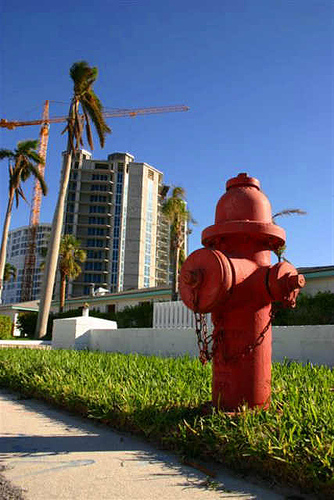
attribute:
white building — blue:
[56, 150, 176, 302]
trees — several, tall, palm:
[44, 69, 77, 313]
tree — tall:
[0, 136, 48, 298]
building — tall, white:
[51, 142, 185, 354]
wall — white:
[55, 303, 330, 361]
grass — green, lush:
[2, 358, 332, 467]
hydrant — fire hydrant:
[174, 162, 297, 422]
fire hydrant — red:
[170, 164, 309, 412]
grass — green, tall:
[110, 354, 171, 415]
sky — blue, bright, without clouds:
[208, 47, 278, 130]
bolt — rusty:
[178, 455, 221, 477]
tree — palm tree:
[2, 121, 37, 282]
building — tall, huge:
[66, 151, 163, 293]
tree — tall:
[34, 58, 112, 339]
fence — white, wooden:
[153, 300, 212, 328]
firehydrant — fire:
[178, 163, 307, 404]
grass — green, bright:
[2, 345, 334, 489]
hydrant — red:
[173, 164, 308, 414]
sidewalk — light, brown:
[3, 365, 328, 495]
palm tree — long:
[34, 56, 110, 346]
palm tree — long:
[3, 135, 48, 298]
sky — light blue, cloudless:
[2, 2, 331, 264]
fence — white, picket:
[151, 298, 212, 330]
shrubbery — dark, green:
[269, 291, 332, 327]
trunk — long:
[33, 139, 74, 338]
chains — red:
[189, 286, 286, 364]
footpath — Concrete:
[0, 389, 307, 498]